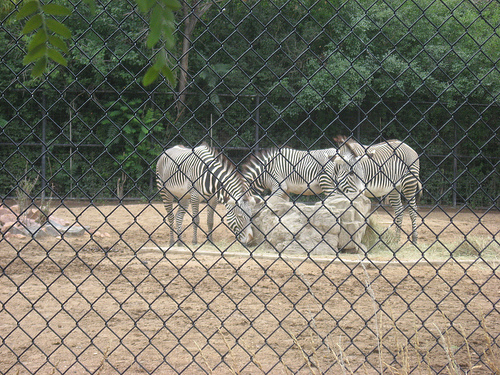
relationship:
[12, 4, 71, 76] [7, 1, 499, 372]
leaves hanging in front of fence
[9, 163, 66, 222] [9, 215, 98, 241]
weeds growing by rocks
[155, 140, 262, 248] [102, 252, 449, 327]
stripes zebra grazing off ground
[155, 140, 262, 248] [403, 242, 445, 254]
stripes zebra eating grass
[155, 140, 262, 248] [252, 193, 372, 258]
stripes zebra near rocks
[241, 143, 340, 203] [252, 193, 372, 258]
stripes zebra near rocks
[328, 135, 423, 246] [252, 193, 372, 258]
stripes zebra near rocks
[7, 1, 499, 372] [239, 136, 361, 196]
fence behind zebra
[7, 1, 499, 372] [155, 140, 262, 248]
fence behind stripes zebra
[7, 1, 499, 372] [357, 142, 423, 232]
fence behind zebra